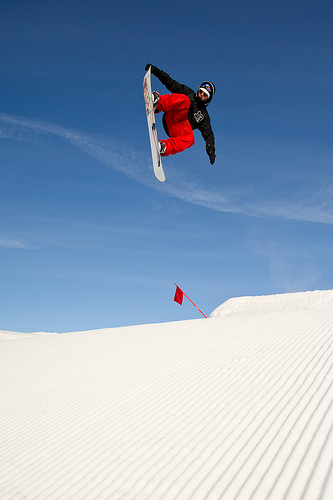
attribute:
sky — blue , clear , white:
[2, 2, 327, 336]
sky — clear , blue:
[20, 278, 205, 321]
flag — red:
[173, 283, 209, 320]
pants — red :
[154, 90, 195, 159]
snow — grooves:
[5, 326, 331, 409]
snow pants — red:
[155, 92, 194, 156]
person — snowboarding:
[139, 54, 224, 172]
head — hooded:
[192, 77, 219, 109]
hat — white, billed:
[199, 84, 213, 99]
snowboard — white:
[141, 64, 166, 182]